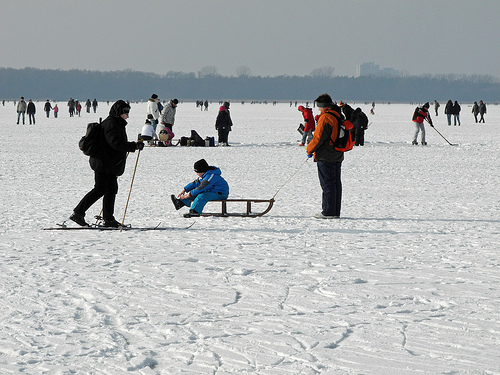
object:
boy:
[168, 158, 230, 217]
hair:
[116, 99, 130, 117]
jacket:
[303, 108, 352, 163]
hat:
[420, 101, 431, 110]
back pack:
[332, 116, 358, 152]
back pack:
[411, 106, 419, 124]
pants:
[310, 152, 345, 221]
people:
[68, 99, 145, 230]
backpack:
[76, 122, 104, 158]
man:
[408, 99, 436, 149]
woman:
[304, 92, 355, 221]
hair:
[311, 93, 333, 109]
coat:
[182, 167, 230, 199]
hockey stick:
[422, 117, 460, 147]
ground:
[0, 100, 499, 373]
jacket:
[86, 116, 136, 178]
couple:
[13, 95, 37, 126]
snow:
[0, 100, 499, 375]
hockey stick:
[120, 138, 145, 234]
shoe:
[168, 192, 187, 211]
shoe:
[181, 210, 201, 218]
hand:
[133, 139, 146, 151]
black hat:
[191, 158, 209, 175]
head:
[191, 157, 210, 175]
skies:
[40, 207, 198, 232]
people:
[476, 99, 487, 123]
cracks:
[219, 285, 243, 310]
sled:
[188, 197, 278, 219]